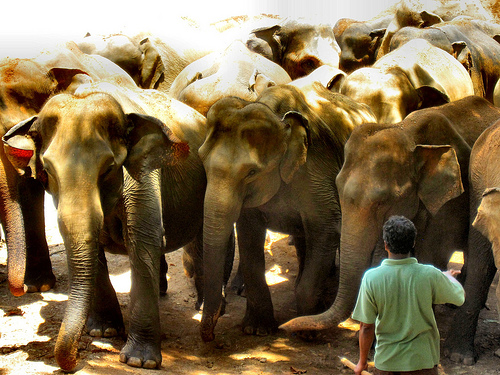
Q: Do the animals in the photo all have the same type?
A: Yes, all the animals are elephants.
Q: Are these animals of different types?
A: No, all the animals are elephants.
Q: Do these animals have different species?
A: No, all the animals are elephants.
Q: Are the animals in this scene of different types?
A: No, all the animals are elephants.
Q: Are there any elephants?
A: Yes, there are elephants.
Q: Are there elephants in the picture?
A: Yes, there are elephants.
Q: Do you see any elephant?
A: Yes, there are elephants.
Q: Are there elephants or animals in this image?
A: Yes, there are elephants.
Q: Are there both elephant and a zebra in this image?
A: No, there are elephants but no zebras.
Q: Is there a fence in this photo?
A: No, there are no fences.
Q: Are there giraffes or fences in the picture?
A: No, there are no fences or giraffes.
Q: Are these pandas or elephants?
A: These are elephants.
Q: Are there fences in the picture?
A: No, there are no fences.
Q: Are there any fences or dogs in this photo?
A: No, there are no fences or dogs.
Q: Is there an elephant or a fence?
A: Yes, there are elephants.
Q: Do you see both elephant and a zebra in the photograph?
A: No, there are elephants but no zebras.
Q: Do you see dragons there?
A: No, there are no dragons.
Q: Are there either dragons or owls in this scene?
A: No, there are no dragons or owls.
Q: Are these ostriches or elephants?
A: These are elephants.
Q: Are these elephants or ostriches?
A: These are elephants.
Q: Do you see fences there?
A: No, there are no fences.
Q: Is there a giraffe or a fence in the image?
A: No, there are no fences or giraffes.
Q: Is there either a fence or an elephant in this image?
A: Yes, there is an elephant.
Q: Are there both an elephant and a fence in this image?
A: No, there is an elephant but no fences.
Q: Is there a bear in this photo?
A: No, there are no bears.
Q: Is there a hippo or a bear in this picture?
A: No, there are no bears or hippos.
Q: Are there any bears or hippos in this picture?
A: No, there are no bears or hippos.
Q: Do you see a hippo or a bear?
A: No, there are no bears or hippos.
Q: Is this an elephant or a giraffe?
A: This is an elephant.